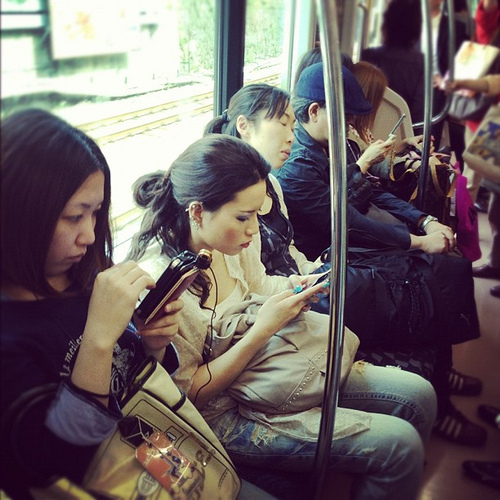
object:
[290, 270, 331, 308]
case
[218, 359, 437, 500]
jeans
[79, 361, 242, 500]
purse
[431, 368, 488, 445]
sneakers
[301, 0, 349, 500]
pole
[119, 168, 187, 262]
ponytail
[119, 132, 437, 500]
woman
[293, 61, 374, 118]
hat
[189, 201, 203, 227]
ear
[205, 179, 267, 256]
face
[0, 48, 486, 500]
people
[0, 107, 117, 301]
hair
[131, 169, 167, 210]
bun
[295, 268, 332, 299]
phone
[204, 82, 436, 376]
woman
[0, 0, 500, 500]
bus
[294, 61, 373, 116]
cap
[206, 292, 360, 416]
bag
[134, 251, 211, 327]
cell phone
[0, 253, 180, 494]
shirt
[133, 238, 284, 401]
shirt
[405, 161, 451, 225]
bag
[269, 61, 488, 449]
man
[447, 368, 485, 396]
shoe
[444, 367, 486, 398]
foot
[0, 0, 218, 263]
window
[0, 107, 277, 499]
woman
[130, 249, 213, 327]
phone